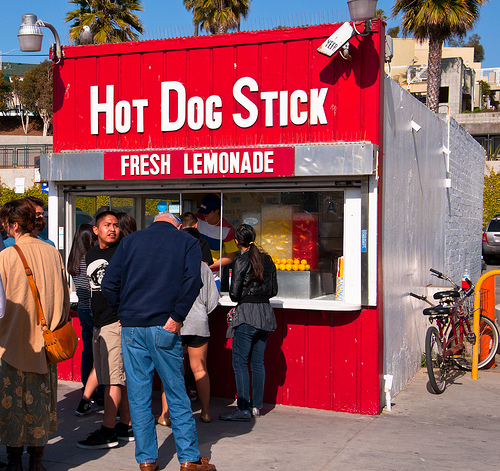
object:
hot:
[90, 84, 148, 134]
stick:
[232, 76, 328, 129]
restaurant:
[46, 21, 484, 415]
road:
[0, 370, 499, 471]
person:
[102, 210, 201, 469]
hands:
[162, 317, 181, 336]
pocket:
[155, 326, 177, 350]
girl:
[221, 224, 276, 421]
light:
[17, 13, 61, 61]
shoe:
[181, 460, 214, 471]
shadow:
[0, 310, 289, 471]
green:
[412, 0, 469, 29]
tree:
[389, 0, 481, 113]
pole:
[472, 270, 500, 379]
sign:
[51, 24, 382, 151]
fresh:
[120, 154, 170, 176]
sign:
[104, 148, 294, 178]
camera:
[316, 21, 354, 60]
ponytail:
[249, 244, 265, 281]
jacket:
[101, 221, 202, 326]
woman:
[0, 199, 71, 470]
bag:
[12, 243, 78, 364]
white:
[337, 21, 353, 43]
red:
[335, 328, 356, 407]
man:
[85, 210, 123, 438]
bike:
[410, 269, 500, 395]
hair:
[0, 199, 46, 236]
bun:
[27, 218, 46, 232]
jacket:
[230, 248, 278, 303]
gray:
[297, 419, 413, 454]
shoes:
[138, 462, 163, 470]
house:
[387, 39, 500, 113]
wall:
[384, 74, 485, 413]